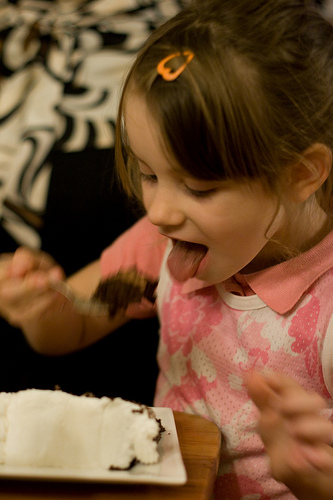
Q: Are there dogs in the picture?
A: No, there are no dogs.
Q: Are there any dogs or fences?
A: No, there are no dogs or fences.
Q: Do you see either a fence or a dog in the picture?
A: No, there are no dogs or fences.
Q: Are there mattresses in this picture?
A: No, there are no mattresses.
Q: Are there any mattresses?
A: No, there are no mattresses.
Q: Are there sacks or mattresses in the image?
A: No, there are no mattresses or sacks.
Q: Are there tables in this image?
A: Yes, there is a table.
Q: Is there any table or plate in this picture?
A: Yes, there is a table.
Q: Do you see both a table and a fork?
A: Yes, there are both a table and a fork.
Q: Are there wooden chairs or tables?
A: Yes, there is a wood table.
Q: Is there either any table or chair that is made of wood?
A: Yes, the table is made of wood.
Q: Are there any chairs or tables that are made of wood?
A: Yes, the table is made of wood.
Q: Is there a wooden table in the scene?
A: Yes, there is a wood table.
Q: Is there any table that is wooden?
A: Yes, there is a table that is wooden.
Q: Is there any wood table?
A: Yes, there is a table that is made of wood.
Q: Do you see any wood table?
A: Yes, there is a table that is made of wood.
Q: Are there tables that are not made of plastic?
A: Yes, there is a table that is made of wood.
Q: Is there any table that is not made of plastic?
A: Yes, there is a table that is made of wood.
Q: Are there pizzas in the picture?
A: No, there are no pizzas.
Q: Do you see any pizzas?
A: No, there are no pizzas.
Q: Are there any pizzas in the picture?
A: No, there are no pizzas.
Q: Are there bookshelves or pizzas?
A: No, there are no pizzas or bookshelves.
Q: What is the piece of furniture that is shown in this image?
A: The piece of furniture is a table.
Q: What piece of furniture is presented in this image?
A: The piece of furniture is a table.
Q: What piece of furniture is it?
A: The piece of furniture is a table.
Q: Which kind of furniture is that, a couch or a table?
A: This is a table.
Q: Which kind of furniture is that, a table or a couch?
A: This is a table.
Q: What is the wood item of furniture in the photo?
A: The piece of furniture is a table.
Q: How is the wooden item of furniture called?
A: The piece of furniture is a table.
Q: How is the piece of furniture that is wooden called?
A: The piece of furniture is a table.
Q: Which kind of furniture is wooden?
A: The furniture is a table.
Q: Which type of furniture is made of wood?
A: The furniture is a table.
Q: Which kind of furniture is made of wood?
A: The furniture is a table.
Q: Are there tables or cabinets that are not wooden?
A: No, there is a table but it is wooden.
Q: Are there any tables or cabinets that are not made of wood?
A: No, there is a table but it is made of wood.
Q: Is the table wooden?
A: Yes, the table is wooden.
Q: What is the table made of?
A: The table is made of wood.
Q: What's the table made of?
A: The table is made of wood.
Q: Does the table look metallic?
A: No, the table is wooden.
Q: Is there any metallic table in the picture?
A: No, there is a table but it is wooden.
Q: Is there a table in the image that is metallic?
A: No, there is a table but it is wooden.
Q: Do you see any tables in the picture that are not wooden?
A: No, there is a table but it is wooden.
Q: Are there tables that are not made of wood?
A: No, there is a table but it is made of wood.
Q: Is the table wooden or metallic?
A: The table is wooden.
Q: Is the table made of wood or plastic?
A: The table is made of wood.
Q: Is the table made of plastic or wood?
A: The table is made of wood.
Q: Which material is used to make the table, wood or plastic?
A: The table is made of wood.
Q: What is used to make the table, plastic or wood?
A: The table is made of wood.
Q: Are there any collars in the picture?
A: Yes, there is a collar.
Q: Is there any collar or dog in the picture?
A: Yes, there is a collar.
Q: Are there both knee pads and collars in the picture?
A: No, there is a collar but no knee pads.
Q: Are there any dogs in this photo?
A: No, there are no dogs.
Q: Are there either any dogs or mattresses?
A: No, there are no dogs or mattresses.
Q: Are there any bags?
A: No, there are no bags.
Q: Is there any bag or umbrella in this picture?
A: No, there are no bags or umbrellas.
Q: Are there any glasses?
A: No, there are no glasses.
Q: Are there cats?
A: No, there are no cats.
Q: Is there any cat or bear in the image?
A: No, there are no cats or bears.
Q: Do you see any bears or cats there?
A: No, there are no cats or bears.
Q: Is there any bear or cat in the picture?
A: No, there are no cats or bears.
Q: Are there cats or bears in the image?
A: No, there are no cats or bears.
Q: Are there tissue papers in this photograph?
A: No, there are no tissue papers.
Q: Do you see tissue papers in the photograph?
A: No, there are no tissue papers.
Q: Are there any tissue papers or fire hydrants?
A: No, there are no tissue papers or fire hydrants.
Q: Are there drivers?
A: No, there are no drivers.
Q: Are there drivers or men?
A: No, there are no drivers or men.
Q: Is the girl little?
A: Yes, the girl is little.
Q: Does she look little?
A: Yes, the girl is little.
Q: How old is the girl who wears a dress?
A: The girl is little.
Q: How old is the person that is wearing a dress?
A: The girl is little.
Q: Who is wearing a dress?
A: The girl is wearing a dress.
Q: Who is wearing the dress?
A: The girl is wearing a dress.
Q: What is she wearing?
A: The girl is wearing a dress.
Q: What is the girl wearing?
A: The girl is wearing a dress.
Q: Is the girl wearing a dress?
A: Yes, the girl is wearing a dress.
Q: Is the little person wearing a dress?
A: Yes, the girl is wearing a dress.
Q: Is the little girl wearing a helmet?
A: No, the girl is wearing a dress.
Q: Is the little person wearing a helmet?
A: No, the girl is wearing a dress.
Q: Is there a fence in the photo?
A: No, there are no fences.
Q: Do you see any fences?
A: No, there are no fences.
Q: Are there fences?
A: No, there are no fences.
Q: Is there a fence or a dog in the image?
A: No, there are no fences or dogs.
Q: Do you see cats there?
A: No, there are no cats.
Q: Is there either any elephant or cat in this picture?
A: No, there are no cats or elephants.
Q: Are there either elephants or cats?
A: No, there are no cats or elephants.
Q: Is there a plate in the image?
A: Yes, there is a plate.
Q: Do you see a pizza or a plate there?
A: Yes, there is a plate.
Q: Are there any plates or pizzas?
A: Yes, there is a plate.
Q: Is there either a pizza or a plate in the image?
A: Yes, there is a plate.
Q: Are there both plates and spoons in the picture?
A: No, there is a plate but no spoons.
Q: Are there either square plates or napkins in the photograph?
A: Yes, there is a square plate.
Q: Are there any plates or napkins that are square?
A: Yes, the plate is square.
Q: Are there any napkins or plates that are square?
A: Yes, the plate is square.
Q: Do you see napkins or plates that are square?
A: Yes, the plate is square.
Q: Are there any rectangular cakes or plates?
A: Yes, there is a rectangular plate.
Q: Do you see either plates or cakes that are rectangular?
A: Yes, the plate is rectangular.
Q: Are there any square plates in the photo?
A: Yes, there is a square plate.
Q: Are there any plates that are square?
A: Yes, there is a plate that is square.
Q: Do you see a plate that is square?
A: Yes, there is a plate that is square.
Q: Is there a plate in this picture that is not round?
A: Yes, there is a square plate.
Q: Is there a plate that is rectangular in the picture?
A: Yes, there is a rectangular plate.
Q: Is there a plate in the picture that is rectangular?
A: Yes, there is a plate that is rectangular.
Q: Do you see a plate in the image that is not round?
A: Yes, there is a rectangular plate.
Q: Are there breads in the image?
A: No, there are no breads.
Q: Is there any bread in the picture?
A: No, there is no breads.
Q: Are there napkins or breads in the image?
A: No, there are no breads or napkins.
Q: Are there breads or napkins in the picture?
A: No, there are no breads or napkins.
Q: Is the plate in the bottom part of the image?
A: Yes, the plate is in the bottom of the image.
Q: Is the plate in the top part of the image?
A: No, the plate is in the bottom of the image.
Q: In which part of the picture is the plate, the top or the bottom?
A: The plate is in the bottom of the image.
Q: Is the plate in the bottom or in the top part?
A: The plate is in the bottom of the image.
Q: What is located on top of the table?
A: The plate is on top of the table.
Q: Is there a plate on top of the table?
A: Yes, there is a plate on top of the table.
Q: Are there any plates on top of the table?
A: Yes, there is a plate on top of the table.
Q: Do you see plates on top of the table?
A: Yes, there is a plate on top of the table.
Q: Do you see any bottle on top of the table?
A: No, there is a plate on top of the table.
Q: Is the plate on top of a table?
A: Yes, the plate is on top of a table.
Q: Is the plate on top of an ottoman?
A: No, the plate is on top of a table.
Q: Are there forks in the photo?
A: Yes, there is a fork.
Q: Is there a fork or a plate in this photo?
A: Yes, there is a fork.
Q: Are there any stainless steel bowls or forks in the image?
A: Yes, there is a stainless steel fork.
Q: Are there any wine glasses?
A: No, there are no wine glasses.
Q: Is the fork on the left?
A: Yes, the fork is on the left of the image.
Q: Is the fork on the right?
A: No, the fork is on the left of the image.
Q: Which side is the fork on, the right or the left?
A: The fork is on the left of the image.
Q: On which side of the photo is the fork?
A: The fork is on the left of the image.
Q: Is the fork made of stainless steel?
A: Yes, the fork is made of stainless steel.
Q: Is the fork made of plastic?
A: No, the fork is made of stainless steel.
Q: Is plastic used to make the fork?
A: No, the fork is made of stainless steel.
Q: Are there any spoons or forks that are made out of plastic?
A: No, there is a fork but it is made of stainless steel.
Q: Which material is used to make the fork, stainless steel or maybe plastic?
A: The fork is made of stainless steel.